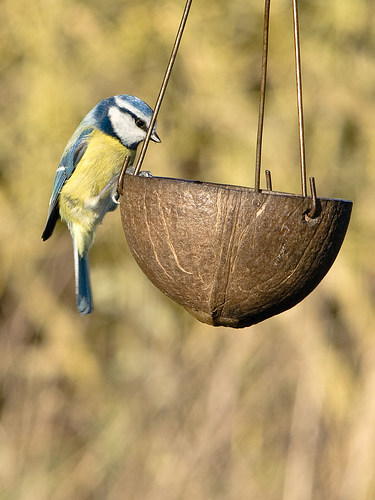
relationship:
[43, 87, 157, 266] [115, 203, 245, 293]
colorful bird perched on feeder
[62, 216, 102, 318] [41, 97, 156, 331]
long blue tail on bird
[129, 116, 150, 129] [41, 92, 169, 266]
small dark eye on bird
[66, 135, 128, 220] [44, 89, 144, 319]
yellow stomach on colorful bird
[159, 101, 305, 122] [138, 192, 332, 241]
hangers on birdfeeder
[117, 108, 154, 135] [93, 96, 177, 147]
stripe on birds head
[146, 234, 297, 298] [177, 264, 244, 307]
birdfeeder shaped like half a nut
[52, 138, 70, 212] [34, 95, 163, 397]
one blue and white wing on bird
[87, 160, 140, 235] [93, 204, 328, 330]
bird's feet hanging onto feeder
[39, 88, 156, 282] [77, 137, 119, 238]
bird yellow in color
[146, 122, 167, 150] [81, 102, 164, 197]
beak black in color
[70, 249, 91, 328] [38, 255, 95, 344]
tail black in color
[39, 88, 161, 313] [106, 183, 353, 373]
bird looking into pot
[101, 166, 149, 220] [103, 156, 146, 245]
legs are brown in color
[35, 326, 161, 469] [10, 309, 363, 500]
plants are seen at background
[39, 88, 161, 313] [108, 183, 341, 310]
bird on a feeder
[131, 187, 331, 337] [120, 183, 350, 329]
feeder bowl shaped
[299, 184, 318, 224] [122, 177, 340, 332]
holder hooked into feeder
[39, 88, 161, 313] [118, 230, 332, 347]
bird looking into feeder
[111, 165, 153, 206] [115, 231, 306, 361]
bird's feet grip feeder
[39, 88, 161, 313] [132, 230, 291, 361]
bird perched on an object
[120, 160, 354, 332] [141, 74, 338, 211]
bowl attached to swing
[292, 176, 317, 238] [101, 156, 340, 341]
hole in bowl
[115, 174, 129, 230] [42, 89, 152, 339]
hook near bird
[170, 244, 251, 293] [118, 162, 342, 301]
texture on bowl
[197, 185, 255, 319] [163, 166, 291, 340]
patch down center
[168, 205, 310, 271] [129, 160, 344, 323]
lines on bowl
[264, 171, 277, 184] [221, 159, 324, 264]
hook behind view